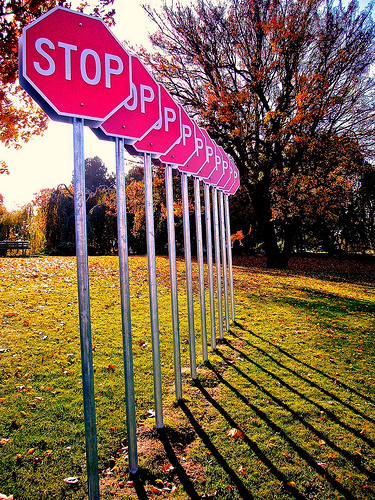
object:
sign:
[22, 6, 133, 123]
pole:
[72, 117, 102, 499]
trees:
[135, 1, 370, 269]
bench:
[10, 247, 42, 267]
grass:
[260, 297, 325, 363]